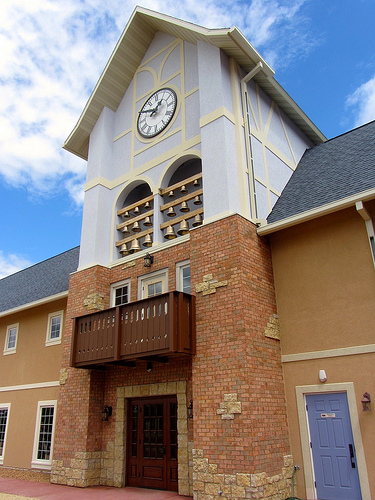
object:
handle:
[347, 443, 355, 472]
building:
[0, 6, 374, 498]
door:
[122, 393, 177, 490]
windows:
[129, 402, 177, 460]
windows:
[112, 267, 193, 307]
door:
[303, 390, 361, 499]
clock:
[133, 87, 177, 138]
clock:
[136, 85, 187, 140]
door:
[129, 386, 183, 485]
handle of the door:
[344, 444, 359, 469]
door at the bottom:
[295, 388, 359, 498]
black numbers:
[138, 92, 174, 136]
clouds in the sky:
[15, 19, 68, 144]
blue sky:
[0, 0, 375, 281]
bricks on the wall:
[190, 216, 294, 500]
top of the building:
[60, 22, 337, 142]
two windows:
[1, 313, 66, 353]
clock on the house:
[135, 85, 187, 140]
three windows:
[105, 259, 196, 306]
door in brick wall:
[112, 385, 186, 499]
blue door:
[303, 389, 363, 499]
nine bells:
[114, 176, 156, 256]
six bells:
[112, 217, 161, 262]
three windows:
[105, 258, 202, 311]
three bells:
[161, 176, 210, 197]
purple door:
[309, 389, 354, 460]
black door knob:
[348, 442, 355, 468]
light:
[354, 391, 374, 422]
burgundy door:
[124, 400, 177, 488]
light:
[99, 398, 122, 423]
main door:
[119, 389, 183, 499]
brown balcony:
[68, 289, 195, 371]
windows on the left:
[0, 402, 62, 470]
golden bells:
[107, 169, 207, 253]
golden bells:
[115, 185, 155, 256]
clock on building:
[127, 79, 188, 143]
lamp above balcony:
[134, 251, 160, 270]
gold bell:
[140, 230, 162, 248]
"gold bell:
[142, 215, 154, 225]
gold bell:
[179, 201, 193, 216]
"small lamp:
[360, 390, 370, 412]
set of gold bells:
[115, 175, 206, 254]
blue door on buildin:
[306, 379, 355, 478]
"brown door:
[125, 395, 177, 493]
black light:
[100, 403, 113, 422]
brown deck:
[69, 324, 166, 351]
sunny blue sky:
[279, 9, 365, 81]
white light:
[313, 367, 333, 382]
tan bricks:
[211, 473, 262, 496]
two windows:
[1, 391, 61, 467]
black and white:
[136, 87, 178, 139]